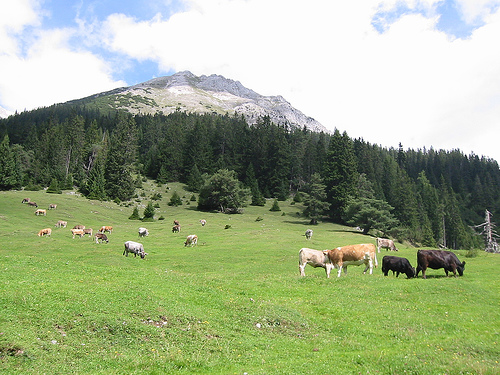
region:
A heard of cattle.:
[18, 192, 472, 290]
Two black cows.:
[383, 248, 473, 285]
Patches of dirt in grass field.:
[37, 307, 332, 358]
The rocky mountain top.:
[94, 68, 320, 130]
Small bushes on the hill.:
[110, 148, 197, 224]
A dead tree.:
[472, 211, 499, 253]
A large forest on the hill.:
[5, 106, 495, 241]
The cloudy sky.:
[21, 5, 141, 79]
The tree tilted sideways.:
[340, 181, 400, 236]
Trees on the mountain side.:
[93, 74, 170, 119]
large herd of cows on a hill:
[19, 188, 479, 304]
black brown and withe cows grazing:
[276, 232, 475, 309]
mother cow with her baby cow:
[380, 246, 470, 289]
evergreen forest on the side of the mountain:
[55, 108, 403, 213]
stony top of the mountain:
[107, 62, 326, 117]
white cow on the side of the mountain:
[118, 235, 150, 261]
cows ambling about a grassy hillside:
[277, 227, 471, 310]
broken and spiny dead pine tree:
[476, 203, 495, 258]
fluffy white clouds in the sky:
[50, 6, 149, 57]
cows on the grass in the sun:
[285, 220, 420, 317]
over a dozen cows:
[22, 187, 473, 311]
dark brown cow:
[408, 241, 472, 281]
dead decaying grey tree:
[470, 208, 498, 255]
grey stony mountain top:
[97, 63, 334, 139]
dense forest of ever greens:
[0, 109, 499, 251]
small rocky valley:
[120, 175, 175, 228]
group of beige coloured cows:
[36, 210, 109, 246]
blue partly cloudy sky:
[1, 0, 497, 156]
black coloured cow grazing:
[380, 252, 421, 280]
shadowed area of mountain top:
[142, 67, 291, 97]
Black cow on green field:
[381, 253, 416, 280]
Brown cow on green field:
[321, 243, 377, 277]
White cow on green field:
[298, 246, 337, 279]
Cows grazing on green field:
[18, 197, 467, 279]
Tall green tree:
[109, 113, 141, 205]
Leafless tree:
[475, 205, 497, 252]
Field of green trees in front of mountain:
[1, 106, 499, 250]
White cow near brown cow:
[296, 241, 376, 277]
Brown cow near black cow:
[323, 243, 415, 277]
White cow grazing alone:
[123, 238, 148, 260]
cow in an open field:
[101, 223, 171, 270]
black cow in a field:
[380, 245, 430, 292]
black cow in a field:
[413, 243, 486, 278]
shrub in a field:
[190, 156, 266, 226]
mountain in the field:
[143, 51, 324, 151]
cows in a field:
[7, 187, 63, 218]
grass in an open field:
[68, 275, 278, 358]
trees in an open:
[383, 133, 464, 230]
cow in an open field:
[192, 200, 210, 230]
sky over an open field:
[80, 14, 486, 64]